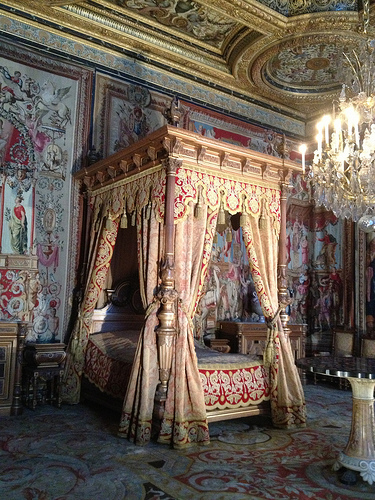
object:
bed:
[61, 120, 309, 452]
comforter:
[196, 363, 268, 412]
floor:
[0, 385, 375, 490]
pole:
[148, 160, 179, 430]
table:
[17, 322, 76, 403]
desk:
[0, 318, 34, 418]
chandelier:
[296, 78, 374, 204]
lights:
[311, 113, 325, 163]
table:
[292, 331, 374, 481]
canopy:
[171, 162, 281, 227]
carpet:
[0, 400, 375, 499]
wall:
[0, 54, 81, 349]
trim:
[0, 0, 235, 93]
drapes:
[156, 207, 221, 457]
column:
[335, 362, 373, 486]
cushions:
[332, 328, 356, 359]